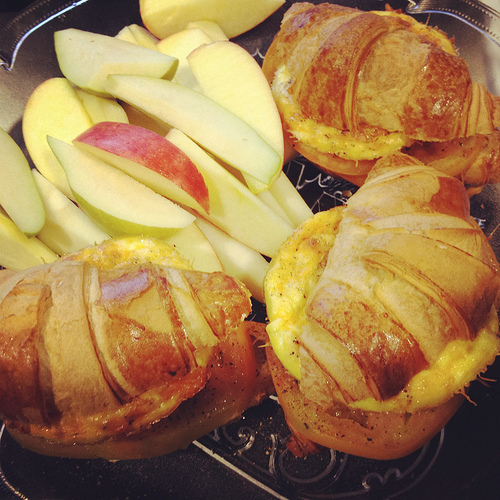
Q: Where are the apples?
A: Next to the croissant egg sandwich.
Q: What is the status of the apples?
A: Sliced.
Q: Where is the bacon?
A: Under the croissant top.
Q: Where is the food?
A: In the clear bowl.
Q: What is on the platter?
A: Three croissant sandwiches and apple slices.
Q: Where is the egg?
A: Below the croissant top.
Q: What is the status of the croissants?
A: Cut in half.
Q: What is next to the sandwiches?
A: Sliced apples.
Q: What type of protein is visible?
A: Eggs.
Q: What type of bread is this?
A: Croissants.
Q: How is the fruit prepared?
A: Raw, sliced, and unpeeled.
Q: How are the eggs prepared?
A: Scrambled.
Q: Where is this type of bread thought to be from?
A: France.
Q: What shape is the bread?
A: Crescent.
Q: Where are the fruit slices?
A: Next to the sandwiches.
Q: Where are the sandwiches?
A: Next to the fruit slices.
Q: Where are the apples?
A: On the tray.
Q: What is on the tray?
A: Food.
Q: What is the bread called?
A: Croissant \.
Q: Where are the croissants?
A: On the tray.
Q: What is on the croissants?
A: Eggs.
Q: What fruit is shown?
A: Apples.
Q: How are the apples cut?
A: Slices.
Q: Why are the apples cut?
A: To eat.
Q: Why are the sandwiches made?
A: For food.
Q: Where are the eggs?
A: In the croissants.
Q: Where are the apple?
A: On the tray.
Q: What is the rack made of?
A: Wire.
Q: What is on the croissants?
A: Eggs.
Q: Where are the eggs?
A: On the croissants.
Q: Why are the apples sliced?
A: To eat.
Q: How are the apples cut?
A: Slices.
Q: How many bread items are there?
A: 3.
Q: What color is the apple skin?
A: Red and green.